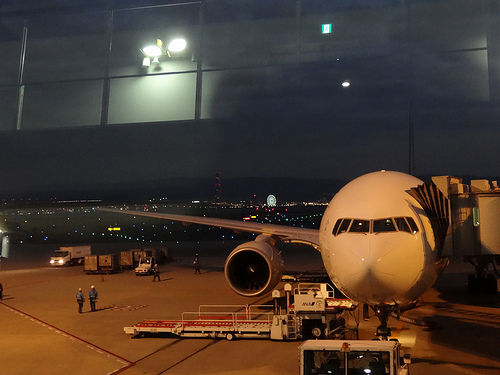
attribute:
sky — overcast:
[57, 129, 442, 176]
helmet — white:
[88, 285, 98, 289]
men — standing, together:
[68, 282, 104, 314]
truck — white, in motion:
[37, 243, 97, 270]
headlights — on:
[137, 32, 194, 64]